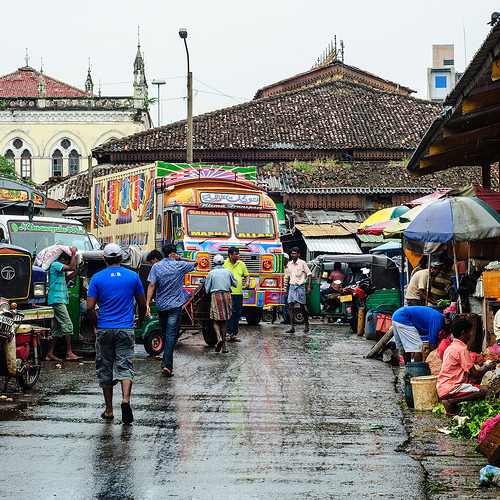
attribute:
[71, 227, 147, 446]
man — barefoot, carrying, barefooted, working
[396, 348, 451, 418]
bucket — white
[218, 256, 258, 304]
shirt — yellow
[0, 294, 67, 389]
scooter — parked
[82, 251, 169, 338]
shirt — blue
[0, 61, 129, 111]
roof — red, wet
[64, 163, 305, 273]
truck — multi-colored, box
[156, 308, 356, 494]
road — wet, slippery, soaked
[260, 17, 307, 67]
sky — gray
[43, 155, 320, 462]
people — working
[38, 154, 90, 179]
window — arched, glass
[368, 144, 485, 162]
umbrella — white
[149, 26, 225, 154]
light — street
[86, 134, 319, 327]
bus — colorful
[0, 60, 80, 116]
top — roof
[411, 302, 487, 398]
boy — young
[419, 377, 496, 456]
vegetable — discarded